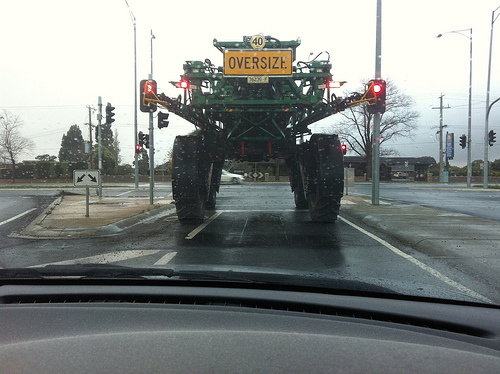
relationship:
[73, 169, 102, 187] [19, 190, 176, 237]
sign on median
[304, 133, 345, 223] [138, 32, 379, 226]
tire on vehicle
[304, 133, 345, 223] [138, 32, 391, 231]
tire on vehicle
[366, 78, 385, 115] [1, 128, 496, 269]
traffic light at intersection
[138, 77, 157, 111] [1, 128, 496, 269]
traffic light at intersection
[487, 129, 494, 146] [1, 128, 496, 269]
traffic light at intersection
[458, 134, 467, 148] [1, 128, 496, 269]
traffic light at intersection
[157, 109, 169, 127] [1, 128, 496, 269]
traffic light at intersection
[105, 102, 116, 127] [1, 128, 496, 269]
traffic light at intersection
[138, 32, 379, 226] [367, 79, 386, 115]
vehicle between traffic light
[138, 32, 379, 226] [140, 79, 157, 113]
vehicle between traffic light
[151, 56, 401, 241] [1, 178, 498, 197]
car at intersection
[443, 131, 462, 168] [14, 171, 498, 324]
sign on road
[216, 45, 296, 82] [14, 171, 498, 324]
sign on road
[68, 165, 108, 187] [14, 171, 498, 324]
sign on road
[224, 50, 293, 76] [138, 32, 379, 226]
sign on vehicle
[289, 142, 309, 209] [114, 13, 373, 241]
tire on truck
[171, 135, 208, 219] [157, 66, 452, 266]
tire on truck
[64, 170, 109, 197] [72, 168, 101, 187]
arrows on sign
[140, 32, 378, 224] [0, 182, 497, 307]
car on road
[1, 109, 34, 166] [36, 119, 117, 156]
tree in a field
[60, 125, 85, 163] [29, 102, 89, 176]
tree in a field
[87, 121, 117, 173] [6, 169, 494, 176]
tree in a field